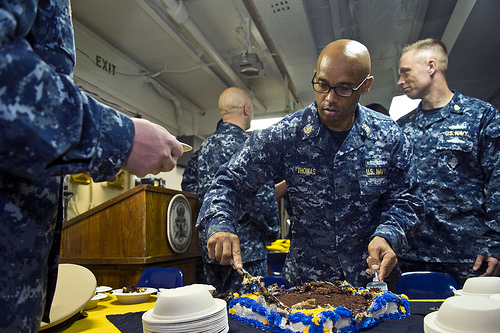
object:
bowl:
[111, 287, 157, 304]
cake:
[121, 284, 148, 293]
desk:
[59, 184, 201, 291]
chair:
[135, 267, 184, 294]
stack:
[422, 296, 499, 331]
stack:
[453, 277, 498, 294]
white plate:
[36, 262, 97, 331]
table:
[36, 292, 500, 332]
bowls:
[141, 284, 226, 324]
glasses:
[311, 69, 371, 98]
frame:
[311, 72, 372, 97]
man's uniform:
[193, 100, 426, 288]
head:
[311, 39, 372, 123]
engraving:
[284, 163, 318, 177]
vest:
[318, 119, 353, 149]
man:
[0, 0, 183, 332]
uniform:
[0, 0, 135, 333]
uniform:
[180, 121, 282, 295]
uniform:
[394, 93, 500, 288]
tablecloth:
[100, 301, 444, 333]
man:
[195, 38, 418, 293]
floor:
[294, 112, 361, 129]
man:
[393, 36, 497, 290]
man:
[180, 86, 283, 292]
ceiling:
[70, 0, 499, 122]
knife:
[228, 259, 289, 310]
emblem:
[165, 193, 193, 254]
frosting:
[265, 290, 373, 310]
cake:
[226, 282, 404, 332]